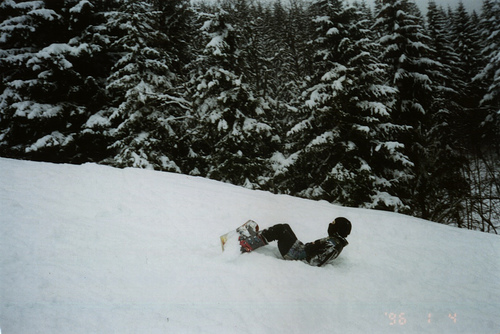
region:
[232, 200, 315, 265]
snowboarder fallen in snow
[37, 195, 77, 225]
white snow on hill side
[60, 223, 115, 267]
white snow on hill side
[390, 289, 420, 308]
white snow on hill side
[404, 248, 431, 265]
white snow on hill side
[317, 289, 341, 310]
white snow on hill side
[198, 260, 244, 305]
white snow on hill side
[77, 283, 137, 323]
white snow on hill side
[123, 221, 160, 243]
white snow on hill side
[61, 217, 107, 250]
white snow on hill side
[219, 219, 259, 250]
snowboard covered in snow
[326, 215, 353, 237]
black ski mask on a person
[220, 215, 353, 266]
person snowboarding in the snow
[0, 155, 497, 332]
slanted hill covered in snow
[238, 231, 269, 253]
dark colored snow boots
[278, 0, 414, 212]
large green tree covered in snow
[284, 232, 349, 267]
winter snow jacket covered in snow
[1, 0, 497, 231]
trees and greenery covered in snow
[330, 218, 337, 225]
eyes of a person on a snowboard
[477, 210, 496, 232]
bare branch on the side of a hill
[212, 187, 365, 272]
person lying on ground in snow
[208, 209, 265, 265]
pair of skis on skier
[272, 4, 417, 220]
snow covered evergreen tree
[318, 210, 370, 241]
black hat on skier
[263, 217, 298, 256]
black snow pants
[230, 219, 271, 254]
grey snow boats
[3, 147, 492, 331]
white snow covered snow slope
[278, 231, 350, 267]
snow jacket on skier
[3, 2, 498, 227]
tall evergreen trees bordering snow slope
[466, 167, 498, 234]
brown tree branches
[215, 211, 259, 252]
The snow board on the man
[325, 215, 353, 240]
The mans ski mask that is black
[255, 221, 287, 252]
The mans black pants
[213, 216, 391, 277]
A man laying down in the snow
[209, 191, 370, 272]
A snowboarder that has fallen over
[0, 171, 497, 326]
Snow on the side of the mountain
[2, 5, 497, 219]
The trees behind the snowbaorder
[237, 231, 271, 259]
The boots of the snowboarder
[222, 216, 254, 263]
A snow board that is covered in snow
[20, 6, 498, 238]
The trees that are covered in snow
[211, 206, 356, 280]
A snowboarder on its back in snow